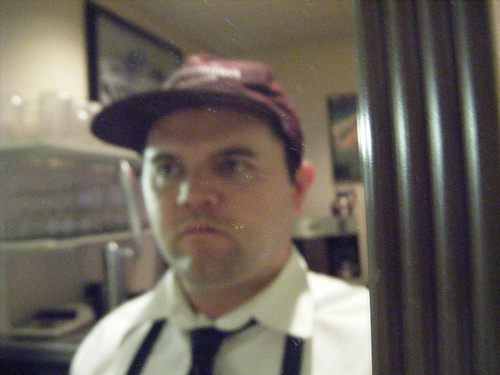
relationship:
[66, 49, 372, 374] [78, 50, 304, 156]
worker wearing hat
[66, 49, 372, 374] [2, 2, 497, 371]
worker in restaurant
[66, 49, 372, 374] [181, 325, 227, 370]
worker has tie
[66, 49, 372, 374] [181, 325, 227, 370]
worker wearing tie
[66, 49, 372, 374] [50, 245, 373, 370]
worker wearing shirt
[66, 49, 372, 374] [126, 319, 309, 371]
worker wearing apron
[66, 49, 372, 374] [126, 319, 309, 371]
worker in apron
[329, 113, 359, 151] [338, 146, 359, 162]
train on tracks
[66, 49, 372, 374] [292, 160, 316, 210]
worker has ear